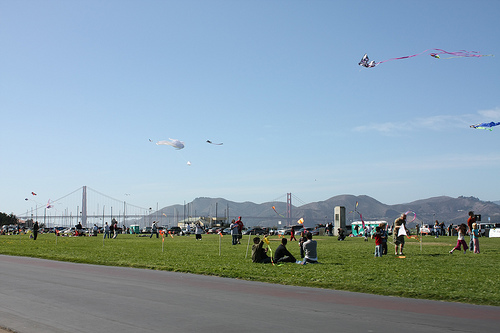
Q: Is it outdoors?
A: Yes, it is outdoors.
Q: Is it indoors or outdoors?
A: It is outdoors.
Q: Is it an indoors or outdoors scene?
A: It is outdoors.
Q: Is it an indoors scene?
A: No, it is outdoors.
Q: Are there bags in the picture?
A: No, there are no bags.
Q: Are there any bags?
A: No, there are no bags.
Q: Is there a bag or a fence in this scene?
A: No, there are no bags or fences.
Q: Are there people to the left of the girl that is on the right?
A: Yes, there is a person to the left of the girl.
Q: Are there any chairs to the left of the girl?
A: No, there is a person to the left of the girl.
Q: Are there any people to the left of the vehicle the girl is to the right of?
A: Yes, there is a person to the left of the vehicle.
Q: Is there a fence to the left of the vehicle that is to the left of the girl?
A: No, there is a person to the left of the vehicle.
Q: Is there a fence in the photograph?
A: No, there are no fences.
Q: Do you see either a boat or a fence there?
A: No, there are no fences or boats.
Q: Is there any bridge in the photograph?
A: Yes, there is a bridge.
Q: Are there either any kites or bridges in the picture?
A: Yes, there is a bridge.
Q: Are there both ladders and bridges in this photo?
A: No, there is a bridge but no ladders.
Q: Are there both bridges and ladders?
A: No, there is a bridge but no ladders.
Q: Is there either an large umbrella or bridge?
A: Yes, there is a large bridge.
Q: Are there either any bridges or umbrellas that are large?
A: Yes, the bridge is large.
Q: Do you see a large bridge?
A: Yes, there is a large bridge.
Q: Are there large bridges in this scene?
A: Yes, there is a large bridge.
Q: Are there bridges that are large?
A: Yes, there is a bridge that is large.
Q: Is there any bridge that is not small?
A: Yes, there is a large bridge.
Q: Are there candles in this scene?
A: No, there are no candles.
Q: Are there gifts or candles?
A: No, there are no candles or gifts.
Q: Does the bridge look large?
A: Yes, the bridge is large.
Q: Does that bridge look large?
A: Yes, the bridge is large.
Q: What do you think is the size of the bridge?
A: The bridge is large.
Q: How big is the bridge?
A: The bridge is large.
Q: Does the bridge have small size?
A: No, the bridge is large.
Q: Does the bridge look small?
A: No, the bridge is large.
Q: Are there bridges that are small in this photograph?
A: No, there is a bridge but it is large.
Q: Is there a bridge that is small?
A: No, there is a bridge but it is large.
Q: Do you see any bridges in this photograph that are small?
A: No, there is a bridge but it is large.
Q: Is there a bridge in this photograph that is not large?
A: No, there is a bridge but it is large.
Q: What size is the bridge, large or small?
A: The bridge is large.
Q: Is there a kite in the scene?
A: Yes, there is a kite.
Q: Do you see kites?
A: Yes, there is a kite.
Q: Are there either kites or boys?
A: Yes, there is a kite.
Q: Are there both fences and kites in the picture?
A: No, there is a kite but no fences.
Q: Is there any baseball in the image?
A: No, there are no baseballs.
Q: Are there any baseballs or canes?
A: No, there are no baseballs or canes.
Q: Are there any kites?
A: Yes, there is a kite.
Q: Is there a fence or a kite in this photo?
A: Yes, there is a kite.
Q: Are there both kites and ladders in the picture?
A: No, there is a kite but no ladders.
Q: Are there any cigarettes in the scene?
A: No, there are no cigarettes.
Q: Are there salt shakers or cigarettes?
A: No, there are no cigarettes or salt shakers.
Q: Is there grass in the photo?
A: Yes, there is grass.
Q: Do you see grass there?
A: Yes, there is grass.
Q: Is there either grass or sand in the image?
A: Yes, there is grass.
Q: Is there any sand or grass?
A: Yes, there is grass.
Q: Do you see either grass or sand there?
A: Yes, there is grass.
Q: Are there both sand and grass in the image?
A: No, there is grass but no sand.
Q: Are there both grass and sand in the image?
A: No, there is grass but no sand.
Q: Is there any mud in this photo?
A: No, there is no mud.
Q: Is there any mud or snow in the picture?
A: No, there are no mud or snow.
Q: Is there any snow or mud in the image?
A: No, there are no mud or snow.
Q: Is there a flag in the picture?
A: Yes, there is a flag.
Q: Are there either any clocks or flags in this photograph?
A: Yes, there is a flag.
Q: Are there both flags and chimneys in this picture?
A: No, there is a flag but no chimneys.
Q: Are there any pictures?
A: No, there are no pictures.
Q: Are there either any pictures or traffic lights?
A: No, there are no pictures or traffic lights.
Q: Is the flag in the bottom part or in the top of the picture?
A: The flag is in the bottom of the image.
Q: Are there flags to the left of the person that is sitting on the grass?
A: Yes, there is a flag to the left of the person.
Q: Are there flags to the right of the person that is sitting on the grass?
A: No, the flag is to the left of the person.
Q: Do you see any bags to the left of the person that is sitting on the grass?
A: No, there is a flag to the left of the person.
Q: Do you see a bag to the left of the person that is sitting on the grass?
A: No, there is a flag to the left of the person.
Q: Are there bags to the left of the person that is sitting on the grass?
A: No, there is a flag to the left of the person.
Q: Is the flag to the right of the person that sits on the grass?
A: No, the flag is to the left of the person.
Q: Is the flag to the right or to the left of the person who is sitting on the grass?
A: The flag is to the left of the person.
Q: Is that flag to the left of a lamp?
A: No, the flag is to the left of a vehicle.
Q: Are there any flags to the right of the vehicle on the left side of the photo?
A: Yes, there is a flag to the right of the vehicle.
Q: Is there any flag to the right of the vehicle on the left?
A: Yes, there is a flag to the right of the vehicle.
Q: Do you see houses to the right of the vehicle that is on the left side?
A: No, there is a flag to the right of the vehicle.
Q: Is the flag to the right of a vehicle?
A: Yes, the flag is to the right of a vehicle.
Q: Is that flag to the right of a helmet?
A: No, the flag is to the right of a vehicle.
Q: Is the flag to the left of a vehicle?
A: Yes, the flag is to the left of a vehicle.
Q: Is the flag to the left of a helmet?
A: No, the flag is to the left of a vehicle.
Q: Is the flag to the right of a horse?
A: No, the flag is to the right of a person.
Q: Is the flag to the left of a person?
A: No, the flag is to the right of a person.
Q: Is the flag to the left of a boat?
A: No, the flag is to the left of a person.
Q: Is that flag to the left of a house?
A: No, the flag is to the left of a person.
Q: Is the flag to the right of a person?
A: No, the flag is to the left of a person.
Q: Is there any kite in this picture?
A: Yes, there is a kite.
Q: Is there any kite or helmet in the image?
A: Yes, there is a kite.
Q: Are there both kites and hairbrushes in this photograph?
A: No, there is a kite but no hairbrushes.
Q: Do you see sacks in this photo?
A: No, there are no sacks.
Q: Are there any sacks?
A: No, there are no sacks.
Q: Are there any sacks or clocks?
A: No, there are no sacks or clocks.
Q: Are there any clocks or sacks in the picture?
A: No, there are no sacks or clocks.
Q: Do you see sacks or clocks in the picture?
A: No, there are no sacks or clocks.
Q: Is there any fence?
A: No, there are no fences.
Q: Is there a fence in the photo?
A: No, there are no fences.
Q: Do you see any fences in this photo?
A: No, there are no fences.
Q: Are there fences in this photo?
A: No, there are no fences.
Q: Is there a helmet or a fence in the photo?
A: No, there are no fences or helmets.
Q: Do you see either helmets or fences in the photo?
A: No, there are no fences or helmets.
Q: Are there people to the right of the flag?
A: Yes, there is a person to the right of the flag.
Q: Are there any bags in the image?
A: No, there are no bags.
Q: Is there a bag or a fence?
A: No, there are no bags or fences.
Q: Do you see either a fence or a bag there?
A: No, there are no fences or bags.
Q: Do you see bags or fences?
A: No, there are no fences or bags.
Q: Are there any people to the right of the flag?
A: Yes, there is a person to the right of the flag.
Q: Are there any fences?
A: No, there are no fences.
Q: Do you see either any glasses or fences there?
A: No, there are no fences or glasses.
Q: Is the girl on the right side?
A: Yes, the girl is on the right of the image.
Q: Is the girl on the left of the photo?
A: No, the girl is on the right of the image.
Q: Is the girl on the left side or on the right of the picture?
A: The girl is on the right of the image.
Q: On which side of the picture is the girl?
A: The girl is on the right of the image.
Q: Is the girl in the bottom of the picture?
A: Yes, the girl is in the bottom of the image.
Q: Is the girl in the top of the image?
A: No, the girl is in the bottom of the image.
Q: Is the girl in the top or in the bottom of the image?
A: The girl is in the bottom of the image.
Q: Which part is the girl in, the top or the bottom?
A: The girl is in the bottom of the image.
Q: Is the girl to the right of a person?
A: No, the girl is to the left of a person.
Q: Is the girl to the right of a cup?
A: No, the girl is to the right of a person.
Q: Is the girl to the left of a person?
A: No, the girl is to the right of a person.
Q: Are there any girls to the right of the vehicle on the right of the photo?
A: Yes, there is a girl to the right of the vehicle.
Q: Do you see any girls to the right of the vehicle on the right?
A: Yes, there is a girl to the right of the vehicle.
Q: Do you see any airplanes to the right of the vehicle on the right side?
A: No, there is a girl to the right of the vehicle.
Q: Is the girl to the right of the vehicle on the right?
A: Yes, the girl is to the right of the vehicle.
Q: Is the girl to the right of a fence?
A: No, the girl is to the right of the vehicle.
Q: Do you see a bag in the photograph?
A: No, there are no bags.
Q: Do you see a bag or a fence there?
A: No, there are no bags or fences.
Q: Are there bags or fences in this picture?
A: No, there are no bags or fences.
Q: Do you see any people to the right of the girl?
A: Yes, there is a person to the right of the girl.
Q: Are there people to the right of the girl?
A: Yes, there is a person to the right of the girl.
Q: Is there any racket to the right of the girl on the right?
A: No, there is a person to the right of the girl.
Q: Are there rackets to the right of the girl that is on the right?
A: No, there is a person to the right of the girl.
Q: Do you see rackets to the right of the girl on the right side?
A: No, there is a person to the right of the girl.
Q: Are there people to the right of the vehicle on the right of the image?
A: Yes, there is a person to the right of the vehicle.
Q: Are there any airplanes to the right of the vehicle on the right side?
A: No, there is a person to the right of the vehicle.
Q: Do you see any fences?
A: No, there are no fences.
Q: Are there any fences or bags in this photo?
A: No, there are no fences or bags.